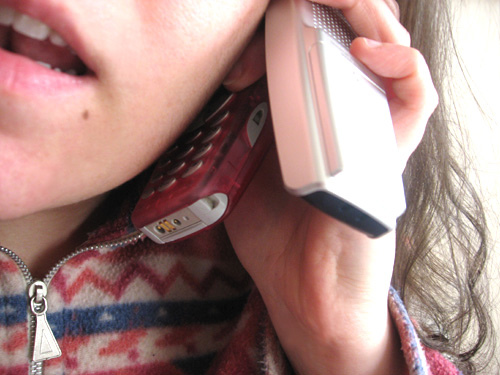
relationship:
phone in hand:
[265, 0, 410, 240] [223, 0, 440, 373]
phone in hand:
[129, 88, 273, 245] [223, 0, 440, 373]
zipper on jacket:
[3, 229, 108, 374] [1, 210, 451, 370]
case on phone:
[133, 73, 275, 244] [132, 72, 272, 246]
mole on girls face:
[78, 106, 95, 121] [3, 0, 232, 218]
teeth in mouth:
[0, 6, 80, 76] [0, 0, 100, 96]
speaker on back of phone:
[294, 7, 359, 48] [255, 3, 413, 244]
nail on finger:
[357, 36, 389, 54] [344, 30, 446, 165]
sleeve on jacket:
[342, 270, 476, 362] [32, 157, 478, 358]